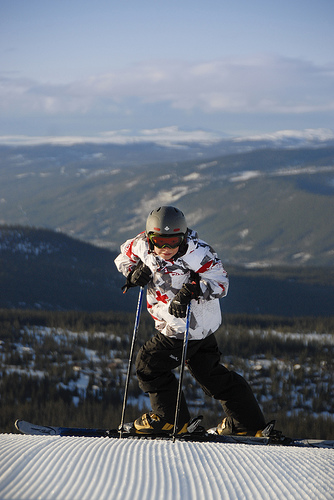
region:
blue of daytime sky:
[0, 1, 333, 64]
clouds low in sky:
[2, 52, 332, 125]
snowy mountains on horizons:
[1, 124, 331, 155]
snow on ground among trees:
[3, 309, 331, 429]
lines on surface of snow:
[1, 433, 332, 497]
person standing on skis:
[13, 205, 327, 444]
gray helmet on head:
[146, 205, 187, 236]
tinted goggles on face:
[152, 231, 185, 248]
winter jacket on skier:
[116, 232, 227, 336]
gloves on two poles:
[132, 269, 192, 318]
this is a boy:
[82, 190, 270, 426]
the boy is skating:
[102, 206, 240, 432]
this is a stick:
[117, 307, 143, 345]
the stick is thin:
[120, 298, 151, 338]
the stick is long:
[121, 298, 153, 340]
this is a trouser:
[196, 342, 222, 373]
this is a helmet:
[148, 205, 182, 232]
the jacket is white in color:
[152, 263, 177, 291]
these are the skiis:
[159, 415, 209, 439]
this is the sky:
[190, 46, 261, 92]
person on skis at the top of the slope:
[15, 206, 325, 443]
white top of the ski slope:
[2, 433, 332, 497]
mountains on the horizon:
[0, 124, 333, 307]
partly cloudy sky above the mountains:
[1, 2, 332, 133]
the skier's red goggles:
[145, 234, 184, 247]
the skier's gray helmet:
[146, 205, 187, 238]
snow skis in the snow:
[14, 421, 299, 445]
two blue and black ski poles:
[117, 284, 194, 441]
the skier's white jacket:
[115, 233, 226, 338]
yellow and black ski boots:
[132, 415, 266, 438]